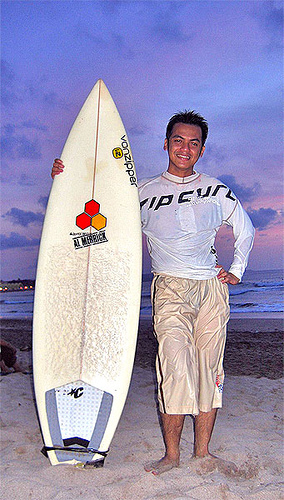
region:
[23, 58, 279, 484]
man holding a surfboard upright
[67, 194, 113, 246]
a logo on a surfboard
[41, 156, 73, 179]
fingers holding a surfboard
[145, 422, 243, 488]
a man bare feet in the sand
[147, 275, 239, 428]
man wearing long surfing wet pants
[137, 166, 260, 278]
a white long sleeve shirt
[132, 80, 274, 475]
a man by the beach at sunset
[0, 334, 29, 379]
person sitting on the sand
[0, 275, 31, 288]
red lights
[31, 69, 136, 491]
a white surfboard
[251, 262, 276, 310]
a cold blue ocean.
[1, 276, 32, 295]
lights are on the ocean.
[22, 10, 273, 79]
a sky is cloudy.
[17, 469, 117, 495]
lots of beige sand.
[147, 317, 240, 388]
a man is wearing beige and black shorts.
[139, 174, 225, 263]
a man is wearing a white and black shirt.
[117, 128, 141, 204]
the surfboard says von zipper.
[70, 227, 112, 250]
the surfboard is from almerrick.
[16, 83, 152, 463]
a beige grey yellow and black surfboard.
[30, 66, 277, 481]
the man is holding a surfboard.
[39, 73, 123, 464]
large white surfboard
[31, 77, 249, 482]
man standing with surfboard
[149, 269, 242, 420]
tan swim shorts with black stripe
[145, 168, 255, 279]
white surfing shirt with Rip Curl Text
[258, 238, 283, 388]
beach during a sunset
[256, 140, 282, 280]
different colored clouds during sunset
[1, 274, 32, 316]
homes and buildings on the beach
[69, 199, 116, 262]
Al Merrick text with 3 hexagons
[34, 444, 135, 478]
ankle strap wrapped around surfboard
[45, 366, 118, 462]
top side of surfboard rudder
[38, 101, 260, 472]
man posing with surfboard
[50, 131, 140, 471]
white surfboard stuck in sand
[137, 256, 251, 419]
man wearing very long white shorts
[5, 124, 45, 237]
clouds in the sky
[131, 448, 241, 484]
sand covering man's feet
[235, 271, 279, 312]
ocean waves crashing to shore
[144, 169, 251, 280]
white shirt with black lettering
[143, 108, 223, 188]
man looking directly at camera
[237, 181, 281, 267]
sky with pink from sun set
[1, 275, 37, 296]
building with lights on in the distance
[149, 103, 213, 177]
young man with brown hair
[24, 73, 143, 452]
long white and red surfboard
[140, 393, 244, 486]
pair of hairy legs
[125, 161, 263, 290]
white surf shirt with logo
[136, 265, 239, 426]
pair of wet surf shorts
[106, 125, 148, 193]
small logo for vonzipper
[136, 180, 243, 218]
large logo for rip curl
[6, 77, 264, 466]
surfer standing with board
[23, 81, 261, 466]
young man with surfboard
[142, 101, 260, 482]
young man standing on beach